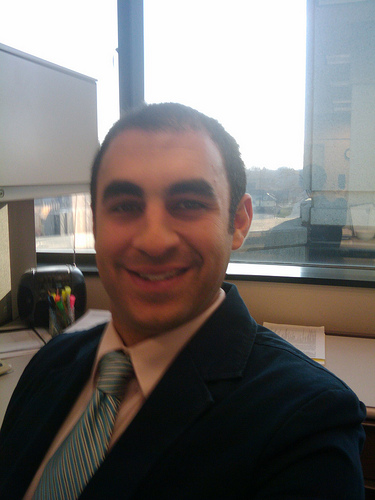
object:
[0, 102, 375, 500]
man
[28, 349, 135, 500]
tie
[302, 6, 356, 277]
reflection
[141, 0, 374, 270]
window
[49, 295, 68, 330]
pens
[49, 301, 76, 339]
cup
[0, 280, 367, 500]
jacket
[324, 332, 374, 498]
cabinet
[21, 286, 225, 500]
shirt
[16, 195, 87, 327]
radio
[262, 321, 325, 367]
paperwork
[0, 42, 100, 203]
cabinet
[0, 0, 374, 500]
office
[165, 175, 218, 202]
eyebrow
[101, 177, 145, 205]
eyebrow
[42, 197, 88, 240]
cityscape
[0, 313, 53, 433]
desk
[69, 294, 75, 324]
highlighters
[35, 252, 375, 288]
ledge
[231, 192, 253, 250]
ear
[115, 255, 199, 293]
smile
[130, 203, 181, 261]
nose